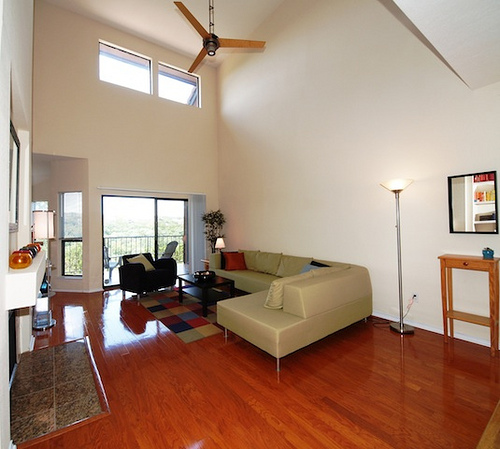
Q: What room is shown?
A: It is a living room.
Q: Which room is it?
A: It is a living room.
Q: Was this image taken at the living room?
A: Yes, it was taken in the living room.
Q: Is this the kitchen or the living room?
A: It is the living room.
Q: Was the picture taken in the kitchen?
A: No, the picture was taken in the living room.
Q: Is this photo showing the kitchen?
A: No, the picture is showing the living room.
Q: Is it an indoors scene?
A: Yes, it is indoors.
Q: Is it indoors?
A: Yes, it is indoors.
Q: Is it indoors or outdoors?
A: It is indoors.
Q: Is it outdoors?
A: No, it is indoors.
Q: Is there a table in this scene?
A: Yes, there is a table.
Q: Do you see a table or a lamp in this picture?
A: Yes, there is a table.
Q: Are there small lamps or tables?
A: Yes, there is a small table.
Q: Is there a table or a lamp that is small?
A: Yes, the table is small.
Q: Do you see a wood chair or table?
A: Yes, there is a wood table.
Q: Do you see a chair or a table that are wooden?
A: Yes, the table is wooden.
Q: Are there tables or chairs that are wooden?
A: Yes, the table is wooden.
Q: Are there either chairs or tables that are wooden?
A: Yes, the table is wooden.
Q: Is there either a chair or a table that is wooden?
A: Yes, the table is wooden.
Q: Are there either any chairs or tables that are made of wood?
A: Yes, the table is made of wood.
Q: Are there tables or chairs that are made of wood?
A: Yes, the table is made of wood.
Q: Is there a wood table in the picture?
A: Yes, there is a wood table.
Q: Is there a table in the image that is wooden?
A: Yes, there is a table that is wooden.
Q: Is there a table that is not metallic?
A: Yes, there is a wooden table.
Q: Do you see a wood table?
A: Yes, there is a table that is made of wood.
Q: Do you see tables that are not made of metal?
A: Yes, there is a table that is made of wood.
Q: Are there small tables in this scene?
A: Yes, there is a small table.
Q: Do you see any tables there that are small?
A: Yes, there is a table that is small.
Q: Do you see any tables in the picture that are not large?
A: Yes, there is a small table.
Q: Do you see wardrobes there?
A: No, there are no wardrobes.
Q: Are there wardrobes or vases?
A: No, there are no wardrobes or vases.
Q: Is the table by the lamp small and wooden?
A: Yes, the table is small and wooden.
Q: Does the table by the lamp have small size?
A: Yes, the table is small.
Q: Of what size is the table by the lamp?
A: The table is small.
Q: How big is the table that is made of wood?
A: The table is small.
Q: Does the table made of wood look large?
A: No, the table is small.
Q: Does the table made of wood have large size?
A: No, the table is small.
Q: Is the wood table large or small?
A: The table is small.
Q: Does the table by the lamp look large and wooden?
A: No, the table is wooden but small.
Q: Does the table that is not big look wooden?
A: Yes, the table is wooden.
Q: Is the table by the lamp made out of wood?
A: Yes, the table is made of wood.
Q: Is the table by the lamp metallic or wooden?
A: The table is wooden.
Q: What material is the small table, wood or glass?
A: The table is made of wood.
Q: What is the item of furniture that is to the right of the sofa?
A: The piece of furniture is a table.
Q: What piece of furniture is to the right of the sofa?
A: The piece of furniture is a table.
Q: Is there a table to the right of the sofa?
A: Yes, there is a table to the right of the sofa.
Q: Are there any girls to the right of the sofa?
A: No, there is a table to the right of the sofa.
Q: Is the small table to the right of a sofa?
A: Yes, the table is to the right of a sofa.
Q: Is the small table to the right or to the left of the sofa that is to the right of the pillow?
A: The table is to the right of the sofa.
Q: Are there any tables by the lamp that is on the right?
A: Yes, there is a table by the lamp.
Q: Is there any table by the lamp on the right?
A: Yes, there is a table by the lamp.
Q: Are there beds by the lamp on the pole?
A: No, there is a table by the lamp.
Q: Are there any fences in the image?
A: No, there are no fences.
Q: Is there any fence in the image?
A: No, there are no fences.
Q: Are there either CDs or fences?
A: No, there are no fences or cds.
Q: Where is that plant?
A: The plant is on the floor.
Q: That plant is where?
A: The plant is on the floor.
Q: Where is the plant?
A: The plant is on the floor.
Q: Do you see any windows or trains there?
A: Yes, there is a window.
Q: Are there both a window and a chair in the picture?
A: Yes, there are both a window and a chair.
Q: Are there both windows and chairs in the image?
A: Yes, there are both a window and a chair.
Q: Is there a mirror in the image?
A: Yes, there is a mirror.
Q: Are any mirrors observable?
A: Yes, there is a mirror.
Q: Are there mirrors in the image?
A: Yes, there is a mirror.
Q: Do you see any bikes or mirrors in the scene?
A: Yes, there is a mirror.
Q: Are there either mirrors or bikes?
A: Yes, there is a mirror.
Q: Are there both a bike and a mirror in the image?
A: No, there is a mirror but no bikes.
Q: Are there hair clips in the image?
A: No, there are no hair clips.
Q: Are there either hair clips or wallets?
A: No, there are no hair clips or wallets.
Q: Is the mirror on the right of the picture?
A: Yes, the mirror is on the right of the image.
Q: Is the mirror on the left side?
A: No, the mirror is on the right of the image.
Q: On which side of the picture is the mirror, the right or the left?
A: The mirror is on the right of the image.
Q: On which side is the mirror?
A: The mirror is on the right of the image.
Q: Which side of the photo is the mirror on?
A: The mirror is on the right of the image.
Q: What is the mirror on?
A: The mirror is on the wall.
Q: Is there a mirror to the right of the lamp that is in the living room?
A: Yes, there is a mirror to the right of the lamp.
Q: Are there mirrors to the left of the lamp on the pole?
A: No, the mirror is to the right of the lamp.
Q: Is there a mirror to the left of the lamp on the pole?
A: No, the mirror is to the right of the lamp.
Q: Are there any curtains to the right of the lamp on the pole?
A: No, there is a mirror to the right of the lamp.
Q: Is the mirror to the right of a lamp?
A: Yes, the mirror is to the right of a lamp.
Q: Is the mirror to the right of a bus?
A: No, the mirror is to the right of a lamp.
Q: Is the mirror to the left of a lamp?
A: No, the mirror is to the right of a lamp.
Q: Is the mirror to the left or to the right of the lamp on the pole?
A: The mirror is to the right of the lamp.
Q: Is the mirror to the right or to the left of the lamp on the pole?
A: The mirror is to the right of the lamp.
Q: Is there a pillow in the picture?
A: Yes, there is a pillow.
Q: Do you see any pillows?
A: Yes, there is a pillow.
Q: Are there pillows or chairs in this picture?
A: Yes, there is a pillow.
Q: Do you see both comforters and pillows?
A: No, there is a pillow but no comforters.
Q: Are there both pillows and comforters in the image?
A: No, there is a pillow but no comforters.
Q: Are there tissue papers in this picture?
A: No, there are no tissue papers.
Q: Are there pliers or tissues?
A: No, there are no tissues or pliers.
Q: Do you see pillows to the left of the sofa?
A: Yes, there is a pillow to the left of the sofa.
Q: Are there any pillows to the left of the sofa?
A: Yes, there is a pillow to the left of the sofa.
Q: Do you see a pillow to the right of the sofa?
A: No, the pillow is to the left of the sofa.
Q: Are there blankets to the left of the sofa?
A: No, there is a pillow to the left of the sofa.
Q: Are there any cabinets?
A: No, there are no cabinets.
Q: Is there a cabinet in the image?
A: No, there are no cabinets.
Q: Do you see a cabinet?
A: No, there are no cabinets.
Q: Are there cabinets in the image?
A: No, there are no cabinets.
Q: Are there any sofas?
A: Yes, there is a sofa.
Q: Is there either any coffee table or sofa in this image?
A: Yes, there is a sofa.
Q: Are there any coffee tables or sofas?
A: Yes, there is a sofa.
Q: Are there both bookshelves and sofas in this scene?
A: No, there is a sofa but no bookshelves.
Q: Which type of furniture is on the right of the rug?
A: The piece of furniture is a sofa.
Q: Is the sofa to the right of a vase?
A: No, the sofa is to the right of the rug.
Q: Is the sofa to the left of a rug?
A: No, the sofa is to the right of a rug.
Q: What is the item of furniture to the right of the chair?
A: The piece of furniture is a sofa.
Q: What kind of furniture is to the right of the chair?
A: The piece of furniture is a sofa.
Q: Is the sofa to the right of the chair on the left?
A: Yes, the sofa is to the right of the chair.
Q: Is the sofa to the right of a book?
A: No, the sofa is to the right of the chair.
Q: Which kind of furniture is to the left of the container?
A: The piece of furniture is a sofa.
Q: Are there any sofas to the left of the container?
A: Yes, there is a sofa to the left of the container.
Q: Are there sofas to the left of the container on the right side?
A: Yes, there is a sofa to the left of the container.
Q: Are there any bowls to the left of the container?
A: No, there is a sofa to the left of the container.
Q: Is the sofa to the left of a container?
A: Yes, the sofa is to the left of a container.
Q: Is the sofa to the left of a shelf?
A: No, the sofa is to the left of a container.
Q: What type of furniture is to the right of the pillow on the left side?
A: The piece of furniture is a sofa.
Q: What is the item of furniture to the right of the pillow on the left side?
A: The piece of furniture is a sofa.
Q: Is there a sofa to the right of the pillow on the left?
A: Yes, there is a sofa to the right of the pillow.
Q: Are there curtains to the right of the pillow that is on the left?
A: No, there is a sofa to the right of the pillow.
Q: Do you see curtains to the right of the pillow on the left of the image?
A: No, there is a sofa to the right of the pillow.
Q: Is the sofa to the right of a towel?
A: No, the sofa is to the right of the pillow.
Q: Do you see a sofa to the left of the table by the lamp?
A: Yes, there is a sofa to the left of the table.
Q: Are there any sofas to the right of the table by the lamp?
A: No, the sofa is to the left of the table.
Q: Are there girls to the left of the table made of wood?
A: No, there is a sofa to the left of the table.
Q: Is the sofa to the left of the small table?
A: Yes, the sofa is to the left of the table.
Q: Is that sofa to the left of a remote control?
A: No, the sofa is to the left of the table.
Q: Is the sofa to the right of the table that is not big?
A: No, the sofa is to the left of the table.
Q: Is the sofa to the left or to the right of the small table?
A: The sofa is to the left of the table.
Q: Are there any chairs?
A: Yes, there is a chair.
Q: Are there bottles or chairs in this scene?
A: Yes, there is a chair.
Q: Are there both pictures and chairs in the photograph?
A: No, there is a chair but no pictures.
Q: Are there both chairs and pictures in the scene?
A: No, there is a chair but no pictures.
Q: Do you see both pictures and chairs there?
A: No, there is a chair but no pictures.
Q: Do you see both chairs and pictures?
A: No, there is a chair but no pictures.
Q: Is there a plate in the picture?
A: No, there are no plates.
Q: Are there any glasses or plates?
A: No, there are no plates or glasses.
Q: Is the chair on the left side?
A: Yes, the chair is on the left of the image.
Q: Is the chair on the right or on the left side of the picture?
A: The chair is on the left of the image.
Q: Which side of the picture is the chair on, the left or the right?
A: The chair is on the left of the image.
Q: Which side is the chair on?
A: The chair is on the left of the image.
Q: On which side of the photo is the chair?
A: The chair is on the left of the image.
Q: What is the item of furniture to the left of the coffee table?
A: The piece of furniture is a chair.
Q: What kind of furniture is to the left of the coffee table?
A: The piece of furniture is a chair.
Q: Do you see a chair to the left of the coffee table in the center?
A: Yes, there is a chair to the left of the coffee table.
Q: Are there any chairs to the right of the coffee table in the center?
A: No, the chair is to the left of the coffee table.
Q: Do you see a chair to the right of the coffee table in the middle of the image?
A: No, the chair is to the left of the coffee table.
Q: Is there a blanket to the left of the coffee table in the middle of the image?
A: No, there is a chair to the left of the coffee table.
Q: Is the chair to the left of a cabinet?
A: No, the chair is to the left of a coffee table.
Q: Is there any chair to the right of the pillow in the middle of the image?
A: No, the chair is to the left of the pillow.